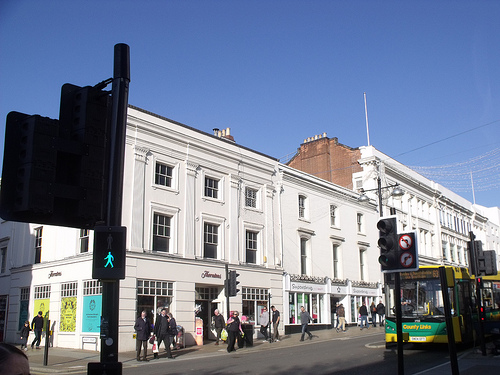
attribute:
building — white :
[5, 91, 381, 373]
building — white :
[156, 126, 390, 307]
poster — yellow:
[59, 295, 78, 334]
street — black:
[2, 330, 458, 373]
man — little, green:
[101, 250, 114, 268]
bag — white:
[145, 331, 162, 353]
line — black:
[367, 105, 497, 167]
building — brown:
[0, 103, 498, 357]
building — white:
[4, 99, 281, 353]